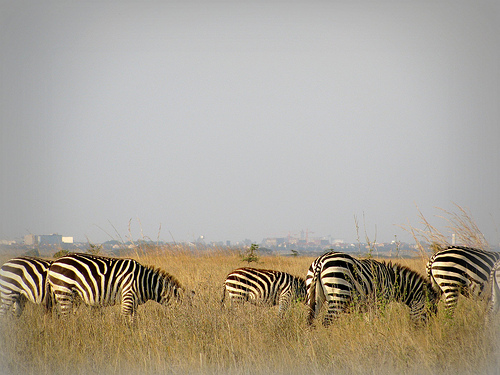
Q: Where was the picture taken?
A: It was taken at the field.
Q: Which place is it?
A: It is a field.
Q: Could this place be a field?
A: Yes, it is a field.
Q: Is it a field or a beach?
A: It is a field.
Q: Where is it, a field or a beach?
A: It is a field.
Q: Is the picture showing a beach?
A: No, the picture is showing a field.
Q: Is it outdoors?
A: Yes, it is outdoors.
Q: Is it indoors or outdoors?
A: It is outdoors.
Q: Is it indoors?
A: No, it is outdoors.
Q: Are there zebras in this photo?
A: Yes, there is a zebra.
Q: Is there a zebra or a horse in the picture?
A: Yes, there is a zebra.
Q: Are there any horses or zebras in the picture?
A: Yes, there is a zebra.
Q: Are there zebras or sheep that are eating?
A: Yes, the zebra is eating.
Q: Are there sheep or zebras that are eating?
A: Yes, the zebra is eating.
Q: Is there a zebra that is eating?
A: Yes, there is a zebra that is eating.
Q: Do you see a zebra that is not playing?
A: Yes, there is a zebra that is eating .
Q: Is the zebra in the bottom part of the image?
A: Yes, the zebra is in the bottom of the image.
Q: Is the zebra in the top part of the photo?
A: No, the zebra is in the bottom of the image.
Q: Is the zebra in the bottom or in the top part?
A: The zebra is in the bottom of the image.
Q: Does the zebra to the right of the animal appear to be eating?
A: Yes, the zebra is eating.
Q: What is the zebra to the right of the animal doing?
A: The zebra is eating.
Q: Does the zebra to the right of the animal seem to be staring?
A: No, the zebra is eating.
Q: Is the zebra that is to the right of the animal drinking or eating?
A: The zebra is eating.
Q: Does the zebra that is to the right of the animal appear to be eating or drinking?
A: The zebra is eating.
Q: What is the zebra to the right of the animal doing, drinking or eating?
A: The zebra is eating.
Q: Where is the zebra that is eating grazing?
A: The zebra is grazing in the field.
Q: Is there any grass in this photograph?
A: Yes, there is grass.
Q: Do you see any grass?
A: Yes, there is grass.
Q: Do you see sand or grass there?
A: Yes, there is grass.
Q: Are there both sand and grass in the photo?
A: No, there is grass but no sand.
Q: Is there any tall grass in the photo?
A: Yes, there is tall grass.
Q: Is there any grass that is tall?
A: Yes, there is grass that is tall.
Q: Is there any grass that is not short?
A: Yes, there is tall grass.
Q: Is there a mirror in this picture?
A: No, there are no mirrors.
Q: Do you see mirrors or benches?
A: No, there are no mirrors or benches.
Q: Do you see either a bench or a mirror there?
A: No, there are no mirrors or benches.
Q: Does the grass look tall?
A: Yes, the grass is tall.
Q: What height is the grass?
A: The grass is tall.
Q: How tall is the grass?
A: The grass is tall.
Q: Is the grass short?
A: No, the grass is tall.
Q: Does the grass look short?
A: No, the grass is tall.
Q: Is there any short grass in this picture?
A: No, there is grass but it is tall.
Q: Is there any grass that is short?
A: No, there is grass but it is tall.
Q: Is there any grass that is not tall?
A: No, there is grass but it is tall.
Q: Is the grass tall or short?
A: The grass is tall.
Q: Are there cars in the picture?
A: No, there are no cars.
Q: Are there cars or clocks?
A: No, there are no cars or clocks.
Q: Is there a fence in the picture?
A: No, there are no fences.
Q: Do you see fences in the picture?
A: No, there are no fences.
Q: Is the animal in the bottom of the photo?
A: Yes, the animal is in the bottom of the image.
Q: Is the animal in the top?
A: No, the animal is in the bottom of the image.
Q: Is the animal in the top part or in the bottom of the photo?
A: The animal is in the bottom of the image.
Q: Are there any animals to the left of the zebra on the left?
A: Yes, there is an animal to the left of the zebra.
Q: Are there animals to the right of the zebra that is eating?
A: No, the animal is to the left of the zebra.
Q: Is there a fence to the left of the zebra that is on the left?
A: No, there is an animal to the left of the zebra.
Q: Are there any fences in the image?
A: No, there are no fences.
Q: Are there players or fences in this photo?
A: No, there are no fences or players.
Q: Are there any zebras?
A: Yes, there is a zebra.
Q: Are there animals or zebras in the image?
A: Yes, there is a zebra.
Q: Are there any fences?
A: No, there are no fences.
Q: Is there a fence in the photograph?
A: No, there are no fences.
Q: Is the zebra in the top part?
A: No, the zebra is in the bottom of the image.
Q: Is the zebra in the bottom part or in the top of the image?
A: The zebra is in the bottom of the image.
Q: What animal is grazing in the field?
A: The animal is a zebra.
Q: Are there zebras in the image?
A: Yes, there is a zebra.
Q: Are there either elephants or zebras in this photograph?
A: Yes, there is a zebra.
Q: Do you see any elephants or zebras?
A: Yes, there is a zebra.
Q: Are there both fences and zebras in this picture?
A: No, there is a zebra but no fences.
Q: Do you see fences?
A: No, there are no fences.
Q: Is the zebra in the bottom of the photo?
A: Yes, the zebra is in the bottom of the image.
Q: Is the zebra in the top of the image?
A: No, the zebra is in the bottom of the image.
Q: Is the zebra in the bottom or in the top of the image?
A: The zebra is in the bottom of the image.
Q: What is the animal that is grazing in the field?
A: The animal is a zebra.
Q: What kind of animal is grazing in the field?
A: The animal is a zebra.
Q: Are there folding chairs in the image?
A: No, there are no folding chairs.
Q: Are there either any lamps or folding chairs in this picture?
A: No, there are no folding chairs or lamps.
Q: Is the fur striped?
A: Yes, the fur is striped.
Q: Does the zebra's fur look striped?
A: Yes, the fur is striped.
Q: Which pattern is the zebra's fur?
A: The fur is striped.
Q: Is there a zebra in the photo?
A: Yes, there is a zebra.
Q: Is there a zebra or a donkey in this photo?
A: Yes, there is a zebra.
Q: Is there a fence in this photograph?
A: No, there are no fences.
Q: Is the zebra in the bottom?
A: Yes, the zebra is in the bottom of the image.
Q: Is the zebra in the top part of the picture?
A: No, the zebra is in the bottom of the image.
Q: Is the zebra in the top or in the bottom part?
A: The zebra is in the bottom of the image.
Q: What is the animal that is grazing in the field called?
A: The animal is a zebra.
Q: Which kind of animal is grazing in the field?
A: The animal is a zebra.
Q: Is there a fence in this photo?
A: No, there are no fences.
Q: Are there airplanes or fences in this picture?
A: No, there are no fences or airplanes.